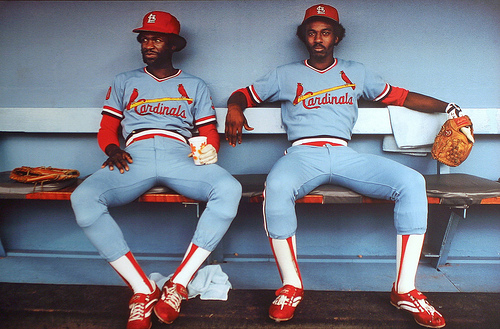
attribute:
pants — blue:
[54, 137, 242, 278]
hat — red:
[298, 4, 343, 31]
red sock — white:
[390, 226, 428, 296]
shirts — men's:
[93, 57, 408, 144]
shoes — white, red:
[121, 277, 158, 327]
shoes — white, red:
[151, 273, 191, 321]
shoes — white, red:
[266, 280, 308, 321]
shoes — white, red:
[385, 279, 446, 327]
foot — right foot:
[247, 262, 322, 327]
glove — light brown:
[432, 91, 487, 190]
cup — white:
[183, 131, 216, 165]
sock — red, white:
[106, 247, 159, 297]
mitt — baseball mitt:
[429, 112, 479, 168]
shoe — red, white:
[152, 278, 185, 327]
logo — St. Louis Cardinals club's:
[285, 66, 365, 133]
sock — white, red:
[177, 241, 207, 291]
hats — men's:
[130, 2, 342, 37]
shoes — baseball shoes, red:
[119, 282, 195, 327]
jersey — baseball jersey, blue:
[233, 54, 407, 153]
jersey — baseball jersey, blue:
[88, 64, 232, 154]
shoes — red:
[121, 281, 450, 325]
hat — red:
[302, 4, 340, 26]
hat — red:
[131, 10, 179, 35]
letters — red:
[290, 81, 368, 111]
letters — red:
[124, 94, 196, 124]